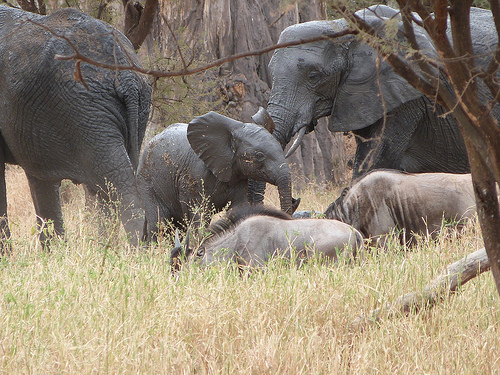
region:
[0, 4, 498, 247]
the herd of elephants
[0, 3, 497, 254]
the elephants in the wild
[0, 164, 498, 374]
the long brown grass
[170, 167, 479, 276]
the animals near the elephants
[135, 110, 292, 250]
the smallest elephant in the group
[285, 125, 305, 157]
the tusk on the elephant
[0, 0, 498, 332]
the trees near the elephants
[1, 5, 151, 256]
the wrinkled skin on the tall elephant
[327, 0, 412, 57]
the small area of green leaves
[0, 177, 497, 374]
the small areas of tall green grass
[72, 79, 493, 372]
elephants in a field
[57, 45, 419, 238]
elephants in a field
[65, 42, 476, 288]
elephants in a grass field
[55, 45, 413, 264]
elephants in tall grass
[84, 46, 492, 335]
elephants in a tall grass field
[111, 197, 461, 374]
a field of tall grass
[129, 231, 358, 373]
a field of grass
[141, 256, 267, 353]
a field of green grass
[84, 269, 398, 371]
a field of tall green grass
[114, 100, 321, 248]
this is an elephant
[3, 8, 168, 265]
this is an elephant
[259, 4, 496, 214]
this is an elephant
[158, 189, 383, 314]
this is a water buck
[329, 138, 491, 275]
this is a water buck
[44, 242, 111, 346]
the grass is long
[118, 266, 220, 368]
the grass is long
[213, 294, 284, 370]
the grass is long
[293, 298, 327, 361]
the grass is long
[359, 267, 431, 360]
the grass is long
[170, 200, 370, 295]
wildebeest with black mane laying in grass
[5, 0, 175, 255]
rear view of large grey elephant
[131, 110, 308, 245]
baby elephant over wildebeest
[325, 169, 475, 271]
grey wildebeest standing in grass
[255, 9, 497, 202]
large gray adult elephant standing near baby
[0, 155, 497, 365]
tall brown and green grasses with animals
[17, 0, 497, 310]
bare and almost leaflss tree in foreground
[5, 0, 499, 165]
leafless trees in background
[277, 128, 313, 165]
long white tusk on elephant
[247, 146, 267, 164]
closed eyelid of baby elephant